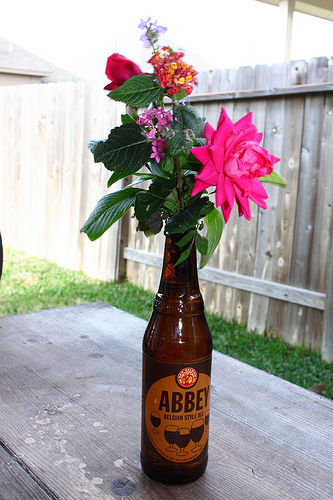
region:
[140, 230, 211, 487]
The beer bottle is being reused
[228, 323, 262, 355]
The green lawn in the shade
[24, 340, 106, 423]
The table is wooden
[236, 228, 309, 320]
The fence is wooden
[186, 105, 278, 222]
The flower is bright pink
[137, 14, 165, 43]
The flowers are purple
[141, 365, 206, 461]
Orange beer bottle label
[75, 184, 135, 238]
The leaf is green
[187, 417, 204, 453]
Picture of a filled glass on beer bottle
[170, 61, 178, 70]
A tiny yellow flower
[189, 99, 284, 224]
pink flower in a brown beer bottle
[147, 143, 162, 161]
small pink flower in a cluster of flowers in brown beer bottle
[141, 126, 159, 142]
small pink flower in a cluster of flowers in brown beer bottle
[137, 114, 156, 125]
small pink flower in a cluster of flowers in brown beer bottle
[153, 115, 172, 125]
small pink flower in a cluster of flowers in brown beer bottle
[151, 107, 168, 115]
small pink flower in a cluster of flowers in brown beer bottle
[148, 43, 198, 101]
cluster of orange flowers in brown beer bottle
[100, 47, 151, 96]
large pink flowers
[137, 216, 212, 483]
brown beer bottle used as a vase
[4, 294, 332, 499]
wooden table the vase is sitting on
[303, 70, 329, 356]
wooden plank on wall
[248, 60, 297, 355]
wooden plank on wall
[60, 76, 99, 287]
wooden plank on wall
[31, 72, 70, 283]
wooden plank on wall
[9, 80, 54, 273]
wooden plank on wall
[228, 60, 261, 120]
wooden plank on wall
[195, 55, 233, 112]
wooden plank on wall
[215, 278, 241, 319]
wooden plank on wall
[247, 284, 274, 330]
wooden plank on wall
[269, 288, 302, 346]
wooden plank on wall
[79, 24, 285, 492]
a bouquet of flowers in a beer bottle vase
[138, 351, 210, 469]
the label on a beer bottle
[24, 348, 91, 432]
the grain on a piece of wood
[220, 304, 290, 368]
grass beside a fence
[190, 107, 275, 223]
a bright pink flower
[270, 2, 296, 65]
support post for a porch roof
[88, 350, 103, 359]
the knot in a piece of wood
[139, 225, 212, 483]
a brown glass beer bottle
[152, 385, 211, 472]
label on the bottle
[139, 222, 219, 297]
neck of the bottle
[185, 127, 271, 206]
the flower is pink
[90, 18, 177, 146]
the flowers are small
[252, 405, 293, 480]
the table is wood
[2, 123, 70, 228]
sun on the fence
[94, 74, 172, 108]
leaf of the flower